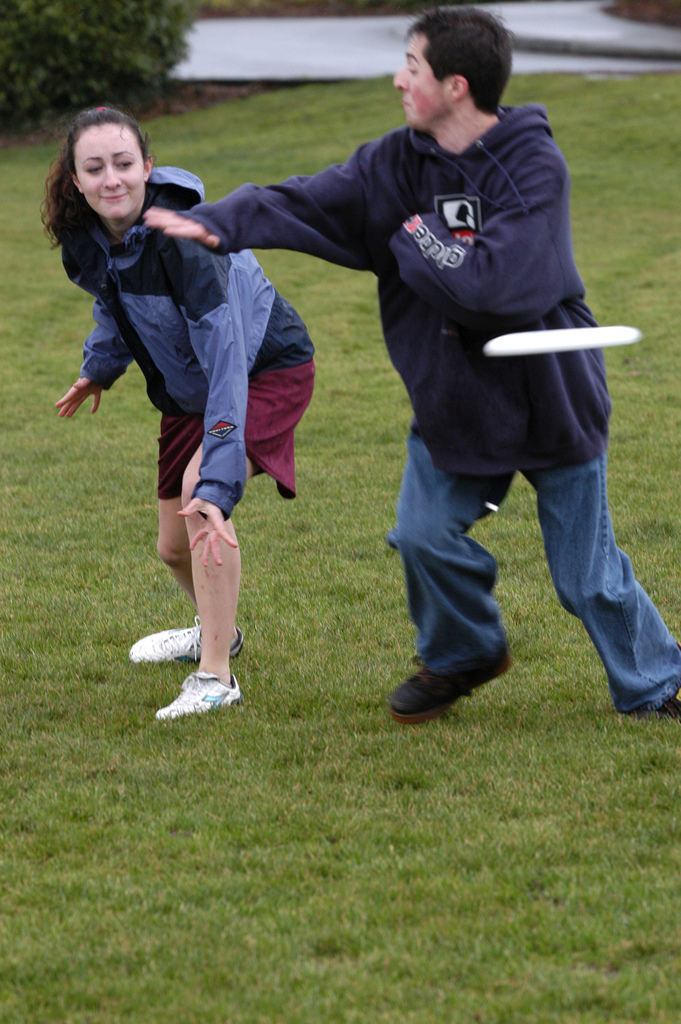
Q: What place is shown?
A: It is a park.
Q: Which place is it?
A: It is a park.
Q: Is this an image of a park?
A: Yes, it is showing a park.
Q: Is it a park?
A: Yes, it is a park.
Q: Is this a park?
A: Yes, it is a park.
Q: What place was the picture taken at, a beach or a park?
A: It was taken at a park.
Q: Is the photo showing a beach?
A: No, the picture is showing a park.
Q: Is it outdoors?
A: Yes, it is outdoors.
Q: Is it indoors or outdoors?
A: It is outdoors.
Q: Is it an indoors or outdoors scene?
A: It is outdoors.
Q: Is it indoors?
A: No, it is outdoors.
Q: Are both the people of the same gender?
A: No, they are both male and female.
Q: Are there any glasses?
A: No, there are no glasses.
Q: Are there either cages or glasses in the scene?
A: No, there are no glasses or cages.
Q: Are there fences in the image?
A: No, there are no fences.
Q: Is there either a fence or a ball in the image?
A: No, there are no fences or balls.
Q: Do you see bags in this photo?
A: No, there are no bags.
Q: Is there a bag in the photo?
A: No, there are no bags.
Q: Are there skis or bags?
A: No, there are no bags or skis.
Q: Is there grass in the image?
A: Yes, there is grass.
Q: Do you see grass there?
A: Yes, there is grass.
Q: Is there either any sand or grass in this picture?
A: Yes, there is grass.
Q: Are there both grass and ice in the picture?
A: No, there is grass but no ice.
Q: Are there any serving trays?
A: No, there are no serving trays.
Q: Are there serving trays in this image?
A: No, there are no serving trays.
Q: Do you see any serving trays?
A: No, there are no serving trays.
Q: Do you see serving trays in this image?
A: No, there are no serving trays.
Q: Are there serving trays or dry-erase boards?
A: No, there are no serving trays or dry-erase boards.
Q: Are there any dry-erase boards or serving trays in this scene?
A: No, there are no serving trays or dry-erase boards.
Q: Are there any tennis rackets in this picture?
A: No, there are no tennis rackets.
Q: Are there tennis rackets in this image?
A: No, there are no tennis rackets.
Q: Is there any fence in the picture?
A: No, there are no fences.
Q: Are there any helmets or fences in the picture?
A: No, there are no fences or helmets.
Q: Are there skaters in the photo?
A: No, there are no skaters.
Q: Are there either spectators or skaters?
A: No, there are no skaters or spectators.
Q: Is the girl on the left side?
A: Yes, the girl is on the left of the image.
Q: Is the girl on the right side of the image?
A: No, the girl is on the left of the image.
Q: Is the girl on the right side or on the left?
A: The girl is on the left of the image.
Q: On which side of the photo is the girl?
A: The girl is on the left of the image.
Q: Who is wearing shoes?
A: The girl is wearing shoes.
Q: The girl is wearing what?
A: The girl is wearing shoes.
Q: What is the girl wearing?
A: The girl is wearing shoes.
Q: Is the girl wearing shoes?
A: Yes, the girl is wearing shoes.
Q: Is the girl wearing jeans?
A: No, the girl is wearing shoes.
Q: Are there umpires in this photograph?
A: No, there are no umpires.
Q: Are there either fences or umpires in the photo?
A: No, there are no umpires or fences.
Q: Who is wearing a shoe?
A: The man is wearing a shoe.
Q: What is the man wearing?
A: The man is wearing a shoe.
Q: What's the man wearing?
A: The man is wearing a shoe.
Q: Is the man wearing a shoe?
A: Yes, the man is wearing a shoe.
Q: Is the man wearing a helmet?
A: No, the man is wearing a shoe.